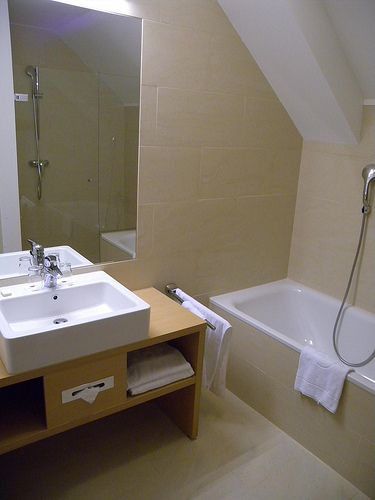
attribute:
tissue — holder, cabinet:
[11, 370, 142, 437]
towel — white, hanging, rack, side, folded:
[173, 298, 260, 374]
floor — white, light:
[204, 428, 296, 479]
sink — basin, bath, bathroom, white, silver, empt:
[0, 256, 134, 368]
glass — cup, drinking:
[18, 285, 120, 355]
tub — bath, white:
[175, 264, 358, 389]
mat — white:
[128, 407, 286, 458]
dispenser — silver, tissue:
[48, 358, 132, 406]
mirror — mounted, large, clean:
[4, 20, 165, 275]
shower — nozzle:
[351, 158, 374, 205]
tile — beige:
[208, 112, 267, 191]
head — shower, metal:
[345, 159, 374, 191]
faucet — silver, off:
[20, 251, 72, 307]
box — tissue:
[46, 359, 127, 422]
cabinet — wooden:
[2, 340, 238, 467]